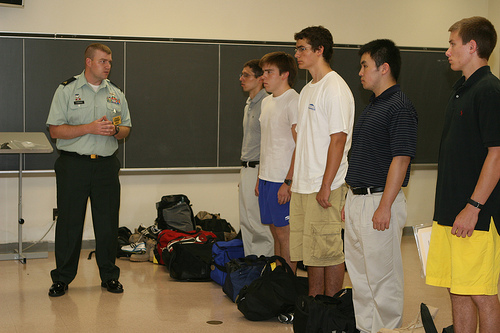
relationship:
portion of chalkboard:
[147, 81, 178, 120] [0, 33, 462, 168]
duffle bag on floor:
[169, 246, 211, 276] [1, 233, 497, 333]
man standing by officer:
[290, 30, 356, 300] [45, 43, 133, 296]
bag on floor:
[231, 255, 308, 319] [1, 233, 497, 333]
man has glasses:
[290, 30, 356, 300] [291, 43, 315, 53]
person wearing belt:
[346, 40, 415, 333] [344, 183, 387, 196]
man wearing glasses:
[238, 59, 267, 258] [291, 43, 315, 53]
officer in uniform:
[45, 43, 133, 296] [45, 71, 130, 279]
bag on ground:
[231, 255, 308, 319] [1, 233, 497, 333]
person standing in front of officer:
[346, 40, 415, 333] [45, 43, 133, 296]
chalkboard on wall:
[0, 33, 462, 168] [0, 2, 494, 241]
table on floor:
[1, 131, 51, 263] [1, 233, 497, 333]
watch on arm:
[466, 196, 483, 211] [449, 132, 499, 213]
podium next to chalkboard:
[1, 131, 51, 263] [0, 33, 462, 168]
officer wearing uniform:
[45, 43, 133, 296] [39, 42, 133, 304]